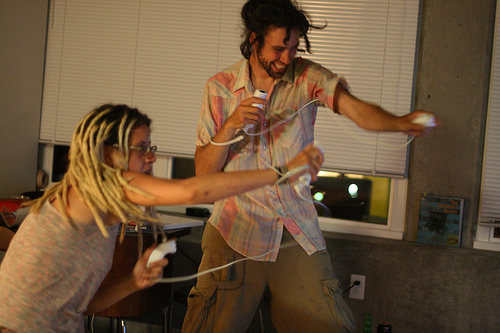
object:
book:
[416, 192, 465, 248]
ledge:
[30, 190, 204, 236]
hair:
[240, 2, 327, 60]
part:
[276, 23, 312, 49]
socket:
[349, 274, 366, 301]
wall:
[13, 250, 499, 332]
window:
[37, 1, 418, 242]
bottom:
[36, 137, 407, 243]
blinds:
[38, 0, 419, 179]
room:
[2, 3, 499, 330]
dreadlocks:
[21, 102, 171, 243]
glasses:
[112, 141, 157, 156]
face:
[107, 125, 156, 178]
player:
[2, 103, 322, 329]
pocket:
[180, 288, 213, 332]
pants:
[182, 221, 359, 332]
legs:
[156, 311, 170, 333]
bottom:
[91, 317, 172, 332]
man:
[182, 1, 437, 332]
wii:
[408, 112, 435, 137]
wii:
[145, 236, 177, 282]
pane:
[171, 154, 392, 227]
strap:
[270, 159, 308, 190]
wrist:
[269, 166, 295, 187]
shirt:
[197, 57, 354, 260]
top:
[1, 181, 120, 332]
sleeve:
[196, 77, 238, 146]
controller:
[246, 88, 267, 132]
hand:
[226, 97, 265, 129]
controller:
[295, 141, 324, 189]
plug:
[353, 280, 362, 286]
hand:
[400, 109, 440, 137]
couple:
[0, 0, 441, 333]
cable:
[338, 281, 358, 294]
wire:
[161, 247, 279, 283]